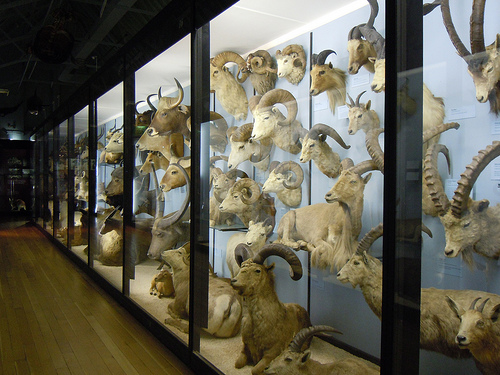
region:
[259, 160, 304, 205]
it is sheep head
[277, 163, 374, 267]
it is a goat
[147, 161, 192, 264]
it is a buffalo head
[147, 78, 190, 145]
it is cow head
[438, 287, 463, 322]
it is goat ear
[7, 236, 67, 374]
it is brown color floor mat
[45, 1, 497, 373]
it is animal museum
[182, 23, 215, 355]
it is a pillar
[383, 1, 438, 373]
it is black color pillar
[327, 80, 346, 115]
it is goat hair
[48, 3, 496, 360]
rows of animal heads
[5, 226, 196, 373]
wood flooring in front of glass case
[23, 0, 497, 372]
glass case full of animal heads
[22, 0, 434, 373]
black frame of the glass case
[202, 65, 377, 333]
reflections on the glass case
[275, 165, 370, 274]
taxidermied animal in a sitting position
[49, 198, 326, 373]
taxidermied animals arranged on the floor of the case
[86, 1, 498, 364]
animal heads with horns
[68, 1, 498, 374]
blue background of glass case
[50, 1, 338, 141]
white ceiling of glass case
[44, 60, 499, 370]
A case full of taxidermy animals.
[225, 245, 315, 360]
A ram seated on the floor.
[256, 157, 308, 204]
A small ram's head on the wall.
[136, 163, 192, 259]
A head with long horns.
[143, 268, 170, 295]
A baby lamb on the floor.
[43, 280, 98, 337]
A brown hardwood floor.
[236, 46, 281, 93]
The head of a mountain goat on the wall.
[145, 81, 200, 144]
A bull's head on the wall.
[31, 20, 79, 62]
A light fixture on the ceiling.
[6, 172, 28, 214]
A case containing a small animal.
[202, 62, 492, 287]
reflection on the glass display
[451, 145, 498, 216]
bumps on the horns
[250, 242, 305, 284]
the horn is curved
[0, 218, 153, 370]
hard wood flooring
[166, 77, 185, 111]
the horn is sharp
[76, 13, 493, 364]
stuffed animals on display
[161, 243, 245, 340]
animal laying down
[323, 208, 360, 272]
long neck hair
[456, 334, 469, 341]
a black nose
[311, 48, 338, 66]
two black curved horns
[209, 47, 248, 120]
mounted animal head next to mounted animal head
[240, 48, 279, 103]
mounted animal head next to mounted animal head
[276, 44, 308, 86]
mounted animal head next to mounted animal head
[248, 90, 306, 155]
mounted animal head next to mounted animal head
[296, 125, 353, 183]
mounted animal head next to mounted animal head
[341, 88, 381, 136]
mounted animal head next to mounted animal head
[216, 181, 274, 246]
mounted animal head next to mounted animal head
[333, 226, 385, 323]
mounted animal head next to mounted animal head